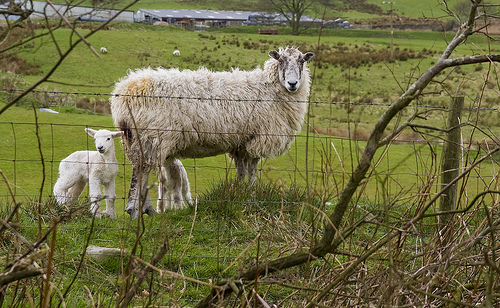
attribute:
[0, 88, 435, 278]
fence — metal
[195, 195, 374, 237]
grass — dried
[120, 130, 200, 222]
legs — back legs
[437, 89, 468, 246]
post — wood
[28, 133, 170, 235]
lamb — white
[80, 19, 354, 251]
sheep — grazing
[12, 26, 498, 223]
grass — field, green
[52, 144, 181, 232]
baby — white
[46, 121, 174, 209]
lamb — nursing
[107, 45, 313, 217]
sheep — behind, mama, standing, large, small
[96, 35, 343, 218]
sheep — baby, white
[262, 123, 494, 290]
branches — dried, around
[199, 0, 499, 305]
stick — dead